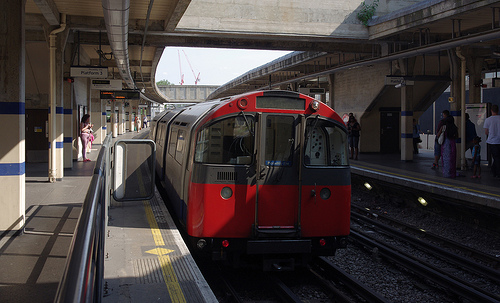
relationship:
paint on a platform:
[142, 201, 184, 301] [104, 128, 214, 301]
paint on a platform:
[153, 188, 216, 300] [104, 180, 214, 301]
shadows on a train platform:
[1, 199, 83, 299] [0, 34, 500, 300]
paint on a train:
[185, 89, 353, 239] [148, 91, 349, 263]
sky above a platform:
[157, 46, 290, 85] [3, 125, 495, 297]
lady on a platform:
[78, 112, 97, 163] [0, 140, 201, 297]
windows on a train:
[193, 112, 348, 171] [148, 91, 349, 263]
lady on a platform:
[78, 112, 97, 163] [0, 125, 144, 299]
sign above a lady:
[68, 63, 111, 79] [78, 112, 97, 163]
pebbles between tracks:
[266, 193, 495, 301] [201, 194, 495, 297]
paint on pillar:
[0, 99, 28, 116] [0, 4, 30, 233]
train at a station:
[148, 87, 353, 278] [10, 9, 492, 299]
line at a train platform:
[141, 198, 185, 301] [0, 129, 221, 299]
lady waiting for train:
[75, 110, 92, 165] [148, 91, 349, 263]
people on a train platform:
[345, 100, 495, 182] [350, 149, 499, 209]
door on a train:
[256, 111, 302, 232] [148, 91, 349, 263]